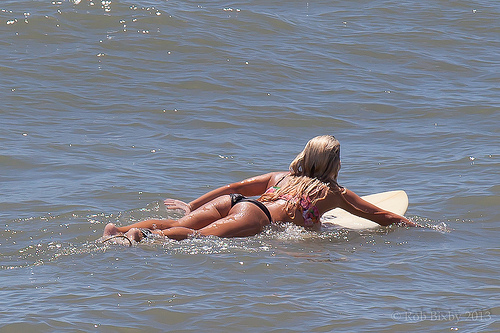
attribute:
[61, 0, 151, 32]
sun — reflects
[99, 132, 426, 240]
woman — blonde, floating, surfer, young, surfing, shining, paddling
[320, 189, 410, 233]
surfboard — white, floating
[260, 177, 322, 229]
shirt — wrinkled, floral, pink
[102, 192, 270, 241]
legs — tan, submerged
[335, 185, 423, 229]
right arm — paddling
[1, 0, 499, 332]
water — calm, blue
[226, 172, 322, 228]
bikini — black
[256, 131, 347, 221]
hair — blonde, wet, long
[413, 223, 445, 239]
hand — paddling